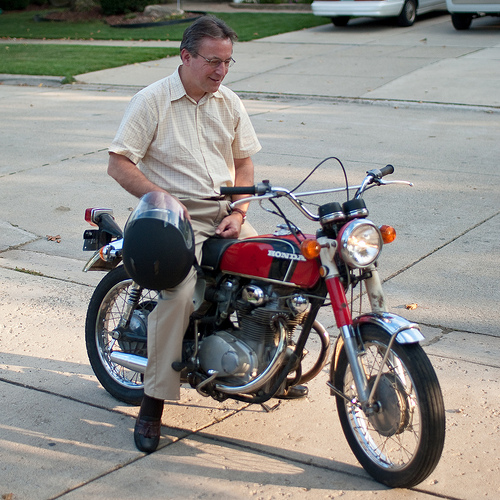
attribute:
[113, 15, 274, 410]
man — smiling, sitting, holding, white, older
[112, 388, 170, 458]
shoe — black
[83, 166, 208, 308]
helmet — black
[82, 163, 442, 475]
motorcycle — red, honda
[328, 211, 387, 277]
light — white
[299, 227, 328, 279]
light — orange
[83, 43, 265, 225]
shirt — yellow, short sleeved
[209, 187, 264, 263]
hand — resting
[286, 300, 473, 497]
wheel — turned, round, black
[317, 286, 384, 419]
pipes — silver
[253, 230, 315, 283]
logo — white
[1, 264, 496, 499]
floor — concrete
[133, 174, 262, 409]
pants — tan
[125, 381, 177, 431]
socks — black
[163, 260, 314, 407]
engine — grey